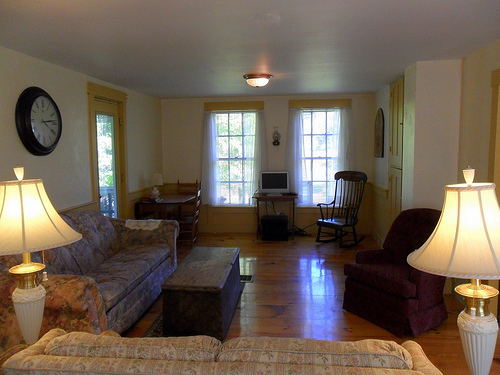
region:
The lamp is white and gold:
[403, 160, 497, 372]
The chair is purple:
[338, 199, 458, 337]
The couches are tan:
[8, 206, 428, 372]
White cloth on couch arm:
[123, 212, 163, 233]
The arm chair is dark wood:
[313, 162, 368, 253]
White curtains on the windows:
[190, 99, 357, 206]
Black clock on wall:
[15, 81, 62, 155]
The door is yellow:
[379, 70, 410, 249]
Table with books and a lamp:
[136, 171, 199, 235]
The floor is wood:
[115, 196, 485, 370]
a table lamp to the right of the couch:
[418, 165, 498, 373]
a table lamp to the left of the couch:
[0, 168, 83, 345]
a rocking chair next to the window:
[315, 163, 370, 254]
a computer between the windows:
[257, 170, 293, 198]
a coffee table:
[159, 240, 248, 321]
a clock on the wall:
[12, 83, 65, 158]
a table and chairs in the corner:
[140, 173, 205, 238]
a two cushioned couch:
[2, 330, 445, 374]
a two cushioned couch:
[0, 193, 193, 333]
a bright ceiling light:
[240, 68, 273, 88]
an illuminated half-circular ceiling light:
[243, 71, 272, 88]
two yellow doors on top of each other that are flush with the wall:
[366, 63, 415, 243]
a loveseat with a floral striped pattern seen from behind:
[3, 328, 440, 374]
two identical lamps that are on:
[0, 167, 497, 373]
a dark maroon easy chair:
[341, 208, 448, 339]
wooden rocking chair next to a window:
[291, 106, 368, 251]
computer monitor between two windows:
[205, 108, 345, 203]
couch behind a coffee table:
[0, 209, 245, 339]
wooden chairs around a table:
[133, 180, 201, 250]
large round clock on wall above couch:
[1, 47, 176, 334]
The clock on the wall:
[13, 86, 67, 157]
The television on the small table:
[257, 169, 292, 199]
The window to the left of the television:
[207, 99, 259, 207]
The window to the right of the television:
[289, 100, 346, 206]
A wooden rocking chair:
[312, 167, 365, 251]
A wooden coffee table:
[161, 245, 243, 339]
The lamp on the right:
[401, 163, 497, 373]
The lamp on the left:
[0, 167, 86, 351]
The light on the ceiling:
[240, 69, 274, 89]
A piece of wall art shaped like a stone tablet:
[372, 107, 385, 160]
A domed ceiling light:
[241, 72, 271, 87]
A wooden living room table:
[157, 240, 241, 332]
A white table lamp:
[404, 166, 498, 373]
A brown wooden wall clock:
[18, 85, 64, 158]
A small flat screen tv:
[260, 167, 290, 196]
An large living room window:
[208, 110, 257, 206]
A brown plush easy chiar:
[345, 203, 453, 338]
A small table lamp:
[145, 170, 165, 197]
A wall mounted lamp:
[265, 126, 283, 148]